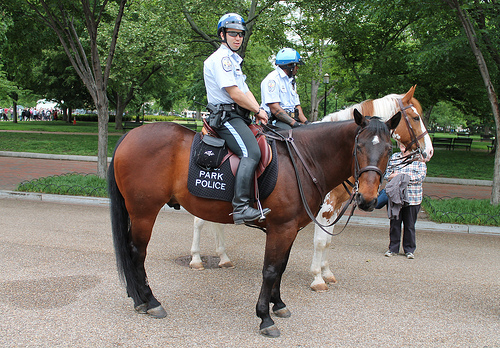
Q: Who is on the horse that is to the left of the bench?
A: The policeman is on the horse.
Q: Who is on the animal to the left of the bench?
A: The policeman is on the horse.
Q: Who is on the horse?
A: The policeman is on the horse.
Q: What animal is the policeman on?
A: The policeman is on the horse.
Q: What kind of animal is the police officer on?
A: The police officer is on the horse.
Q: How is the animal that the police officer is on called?
A: The animal is a horse.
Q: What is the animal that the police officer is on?
A: The animal is a horse.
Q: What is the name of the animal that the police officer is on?
A: The animal is a horse.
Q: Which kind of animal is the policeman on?
A: The police officer is on the horse.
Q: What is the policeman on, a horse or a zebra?
A: The policeman is on a horse.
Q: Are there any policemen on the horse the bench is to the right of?
A: Yes, there is a policeman on the horse.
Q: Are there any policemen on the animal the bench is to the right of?
A: Yes, there is a policeman on the horse.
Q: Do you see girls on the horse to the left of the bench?
A: No, there is a policeman on the horse.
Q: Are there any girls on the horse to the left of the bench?
A: No, there is a policeman on the horse.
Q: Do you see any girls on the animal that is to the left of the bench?
A: No, there is a policeman on the horse.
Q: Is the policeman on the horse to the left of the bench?
A: Yes, the policeman is on the horse.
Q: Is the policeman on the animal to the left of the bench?
A: Yes, the policeman is on the horse.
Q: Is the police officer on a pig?
A: No, the police officer is on the horse.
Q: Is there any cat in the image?
A: No, there are no cats.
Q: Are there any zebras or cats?
A: No, there are no cats or zebras.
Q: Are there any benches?
A: Yes, there is a bench.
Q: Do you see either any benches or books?
A: Yes, there is a bench.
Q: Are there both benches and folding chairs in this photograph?
A: No, there is a bench but no folding chairs.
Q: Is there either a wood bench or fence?
A: Yes, there is a wood bench.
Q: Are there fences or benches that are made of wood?
A: Yes, the bench is made of wood.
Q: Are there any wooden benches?
A: Yes, there is a wood bench.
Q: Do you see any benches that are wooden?
A: Yes, there is a bench that is wooden.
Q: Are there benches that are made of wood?
A: Yes, there is a bench that is made of wood.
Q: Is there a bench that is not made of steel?
A: Yes, there is a bench that is made of wood.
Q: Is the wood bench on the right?
A: Yes, the bench is on the right of the image.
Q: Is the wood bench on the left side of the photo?
A: No, the bench is on the right of the image.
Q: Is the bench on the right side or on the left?
A: The bench is on the right of the image.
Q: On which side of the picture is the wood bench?
A: The bench is on the right of the image.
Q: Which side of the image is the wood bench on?
A: The bench is on the right of the image.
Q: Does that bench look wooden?
A: Yes, the bench is wooden.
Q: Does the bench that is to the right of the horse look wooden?
A: Yes, the bench is wooden.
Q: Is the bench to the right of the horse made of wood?
A: Yes, the bench is made of wood.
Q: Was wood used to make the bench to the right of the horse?
A: Yes, the bench is made of wood.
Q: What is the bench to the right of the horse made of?
A: The bench is made of wood.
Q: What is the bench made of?
A: The bench is made of wood.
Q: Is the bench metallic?
A: No, the bench is wooden.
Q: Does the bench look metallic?
A: No, the bench is wooden.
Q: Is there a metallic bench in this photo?
A: No, there is a bench but it is wooden.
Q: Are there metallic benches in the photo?
A: No, there is a bench but it is wooden.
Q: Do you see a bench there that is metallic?
A: No, there is a bench but it is wooden.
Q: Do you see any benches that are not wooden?
A: No, there is a bench but it is wooden.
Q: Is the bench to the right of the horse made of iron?
A: No, the bench is made of wood.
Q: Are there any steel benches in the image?
A: No, there is a bench but it is made of wood.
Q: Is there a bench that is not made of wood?
A: No, there is a bench but it is made of wood.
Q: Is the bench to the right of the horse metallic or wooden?
A: The bench is wooden.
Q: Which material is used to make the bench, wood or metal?
A: The bench is made of wood.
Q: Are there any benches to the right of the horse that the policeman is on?
A: Yes, there is a bench to the right of the horse.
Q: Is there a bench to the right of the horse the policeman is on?
A: Yes, there is a bench to the right of the horse.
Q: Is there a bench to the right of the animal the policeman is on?
A: Yes, there is a bench to the right of the horse.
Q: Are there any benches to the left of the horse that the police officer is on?
A: No, the bench is to the right of the horse.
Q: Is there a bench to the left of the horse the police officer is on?
A: No, the bench is to the right of the horse.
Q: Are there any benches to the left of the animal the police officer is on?
A: No, the bench is to the right of the horse.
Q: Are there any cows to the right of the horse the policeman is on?
A: No, there is a bench to the right of the horse.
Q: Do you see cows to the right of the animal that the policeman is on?
A: No, there is a bench to the right of the horse.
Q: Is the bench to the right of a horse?
A: Yes, the bench is to the right of a horse.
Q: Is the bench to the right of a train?
A: No, the bench is to the right of a horse.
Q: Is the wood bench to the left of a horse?
A: No, the bench is to the right of a horse.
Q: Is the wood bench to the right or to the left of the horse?
A: The bench is to the right of the horse.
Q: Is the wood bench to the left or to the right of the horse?
A: The bench is to the right of the horse.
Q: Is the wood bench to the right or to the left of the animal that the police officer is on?
A: The bench is to the right of the horse.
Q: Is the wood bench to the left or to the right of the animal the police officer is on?
A: The bench is to the right of the horse.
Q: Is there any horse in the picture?
A: Yes, there is a horse.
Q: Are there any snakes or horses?
A: Yes, there is a horse.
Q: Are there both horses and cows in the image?
A: No, there is a horse but no cows.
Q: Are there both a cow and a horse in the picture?
A: No, there is a horse but no cows.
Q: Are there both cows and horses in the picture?
A: No, there is a horse but no cows.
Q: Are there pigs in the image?
A: No, there are no pigs.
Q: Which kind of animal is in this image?
A: The animal is a horse.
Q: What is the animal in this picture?
A: The animal is a horse.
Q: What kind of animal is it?
A: The animal is a horse.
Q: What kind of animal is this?
A: This is a horse.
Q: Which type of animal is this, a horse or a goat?
A: This is a horse.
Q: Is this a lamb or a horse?
A: This is a horse.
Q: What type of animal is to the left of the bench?
A: The animal is a horse.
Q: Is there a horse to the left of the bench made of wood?
A: Yes, there is a horse to the left of the bench.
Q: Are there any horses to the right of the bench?
A: No, the horse is to the left of the bench.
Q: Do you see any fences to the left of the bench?
A: No, there is a horse to the left of the bench.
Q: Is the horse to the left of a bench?
A: Yes, the horse is to the left of a bench.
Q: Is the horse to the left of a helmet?
A: No, the horse is to the left of a bench.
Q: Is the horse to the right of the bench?
A: No, the horse is to the left of the bench.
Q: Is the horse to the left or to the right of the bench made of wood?
A: The horse is to the left of the bench.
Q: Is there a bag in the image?
A: Yes, there is a bag.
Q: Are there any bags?
A: Yes, there is a bag.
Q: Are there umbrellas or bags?
A: Yes, there is a bag.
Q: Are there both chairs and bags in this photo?
A: No, there is a bag but no chairs.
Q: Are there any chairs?
A: No, there are no chairs.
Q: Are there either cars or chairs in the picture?
A: No, there are no chairs or cars.